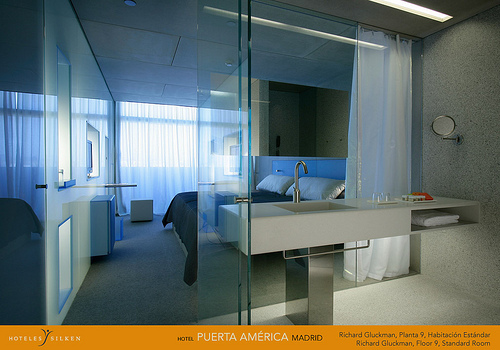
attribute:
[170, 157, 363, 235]
bed — king sized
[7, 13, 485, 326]
room — hotel, very modern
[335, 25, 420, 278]
curtain — white